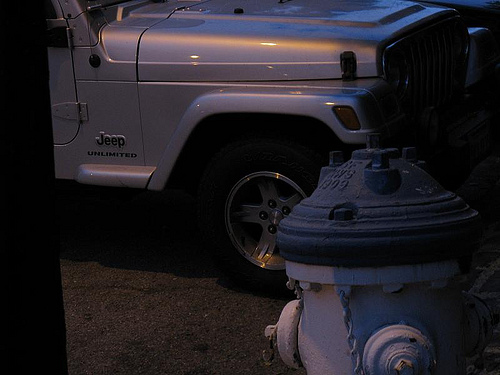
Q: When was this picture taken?
A: Night time.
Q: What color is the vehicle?
A: Grey.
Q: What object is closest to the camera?
A: A fire hydrant.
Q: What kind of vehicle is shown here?
A: Jeep.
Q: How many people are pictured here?
A: Zero.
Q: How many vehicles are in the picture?
A: One.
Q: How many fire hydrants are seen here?
A: One.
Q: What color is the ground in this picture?
A: Black.